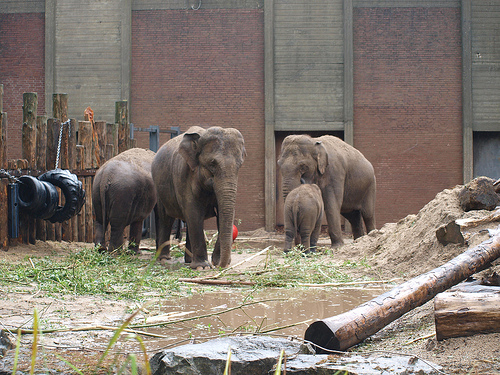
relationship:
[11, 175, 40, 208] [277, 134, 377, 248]
black tire for behind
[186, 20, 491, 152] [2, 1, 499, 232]
building in background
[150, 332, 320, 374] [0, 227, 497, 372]
rocks on ground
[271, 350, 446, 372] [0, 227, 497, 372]
rocks on ground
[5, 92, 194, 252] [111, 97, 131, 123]
elephant enclosure made of post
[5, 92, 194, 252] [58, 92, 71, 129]
elephant enclosure made of post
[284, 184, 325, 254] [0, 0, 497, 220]
baby elephant around building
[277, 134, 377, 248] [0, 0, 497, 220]
behind around building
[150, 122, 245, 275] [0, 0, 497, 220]
elephant around building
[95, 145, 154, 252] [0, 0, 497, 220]
elephant around building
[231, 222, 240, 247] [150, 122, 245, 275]
red object by elephant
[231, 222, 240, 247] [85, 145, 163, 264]
red object by elephant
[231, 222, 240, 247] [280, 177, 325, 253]
red object by elephant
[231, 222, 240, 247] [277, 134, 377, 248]
red object by behind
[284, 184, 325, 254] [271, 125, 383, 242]
baby elephant by elephant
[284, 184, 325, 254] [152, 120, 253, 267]
baby elephant by elephant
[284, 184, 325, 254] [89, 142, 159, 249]
baby elephant by elephant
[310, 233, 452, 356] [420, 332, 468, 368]
log on ground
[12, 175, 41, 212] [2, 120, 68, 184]
black tire on rope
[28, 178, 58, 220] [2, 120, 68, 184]
black tire on rope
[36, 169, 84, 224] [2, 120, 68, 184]
black tire on rope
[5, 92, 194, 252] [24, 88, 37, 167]
elephant enclosure of logs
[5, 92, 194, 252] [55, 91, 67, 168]
elephant enclosure of logs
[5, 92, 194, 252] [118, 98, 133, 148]
elephant enclosure of logs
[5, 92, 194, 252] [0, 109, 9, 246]
elephant enclosure of logs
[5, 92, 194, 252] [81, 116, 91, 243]
elephant enclosure of logs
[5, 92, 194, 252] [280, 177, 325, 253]
elephant enclosure by elephant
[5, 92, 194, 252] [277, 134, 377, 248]
elephant enclosure by behind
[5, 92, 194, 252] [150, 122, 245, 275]
elephant enclosure by elephant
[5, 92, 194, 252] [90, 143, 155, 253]
elephant enclosure by elephant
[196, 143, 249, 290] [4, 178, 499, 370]
trunk touching ground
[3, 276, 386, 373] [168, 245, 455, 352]
pool of water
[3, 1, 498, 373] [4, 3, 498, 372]
elephant enclosure at zoo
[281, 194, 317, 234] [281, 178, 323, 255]
behind of elephant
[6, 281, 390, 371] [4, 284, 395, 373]
puddle of water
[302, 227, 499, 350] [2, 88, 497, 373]
log sitting in enclosure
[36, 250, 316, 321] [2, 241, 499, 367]
grass on ground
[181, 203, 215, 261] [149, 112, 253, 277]
leg of an elephant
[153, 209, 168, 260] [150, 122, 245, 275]
leg of an elephant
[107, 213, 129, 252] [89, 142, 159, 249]
leg of an elephant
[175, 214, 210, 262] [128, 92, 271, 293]
leg of an elephant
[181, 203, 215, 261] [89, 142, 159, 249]
leg of an elephant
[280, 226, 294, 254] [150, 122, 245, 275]
leg of an elephant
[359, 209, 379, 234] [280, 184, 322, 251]
leg of an elephant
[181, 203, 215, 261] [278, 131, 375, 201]
leg of an elephant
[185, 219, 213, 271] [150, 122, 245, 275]
leg of an elephant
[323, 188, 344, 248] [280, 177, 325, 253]
leg of an elephant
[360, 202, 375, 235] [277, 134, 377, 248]
leg of an behind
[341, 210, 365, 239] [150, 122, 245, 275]
leg of an elephant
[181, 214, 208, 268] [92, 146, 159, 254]
leg of an elephant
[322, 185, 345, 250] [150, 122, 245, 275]
leg of an elephant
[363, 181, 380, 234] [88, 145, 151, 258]
leg of an elephant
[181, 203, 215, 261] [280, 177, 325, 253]
leg of an elephant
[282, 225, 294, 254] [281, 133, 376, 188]
leg of an elephant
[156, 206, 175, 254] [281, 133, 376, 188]
leg of an elephant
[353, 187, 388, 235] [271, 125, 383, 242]
leg of an elephant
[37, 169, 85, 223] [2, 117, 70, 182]
black tire hanging from rope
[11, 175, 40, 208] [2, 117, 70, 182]
black tire hanging from rope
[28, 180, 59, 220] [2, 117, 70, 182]
black tire hanging from rope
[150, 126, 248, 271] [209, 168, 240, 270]
elephant has trunk